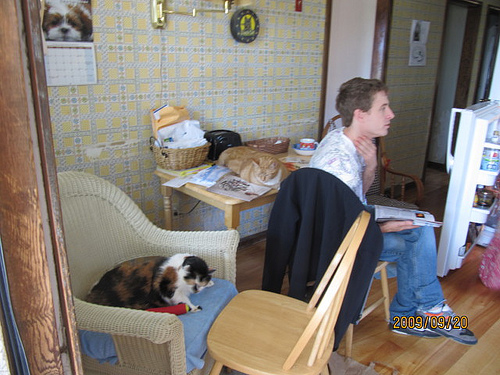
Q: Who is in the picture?
A: A man.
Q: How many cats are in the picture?
A: One.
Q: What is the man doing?
A: Holding his throat.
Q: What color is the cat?
A: Brown, black, and white.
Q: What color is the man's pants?
A: Blue.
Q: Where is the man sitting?
A: In a chair.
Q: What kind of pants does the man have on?
A: Jeans.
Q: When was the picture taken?
A: While the cat was sitting in a chair.